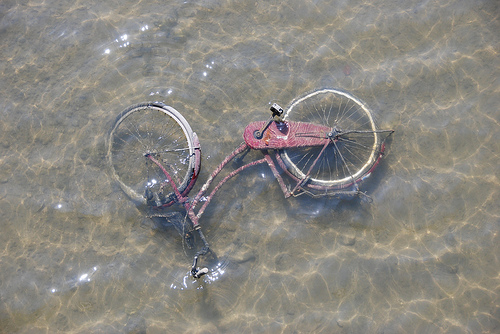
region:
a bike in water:
[101, 87, 392, 274]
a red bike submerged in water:
[103, 88, 389, 278]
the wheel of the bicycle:
[103, 102, 202, 204]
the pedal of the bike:
[253, 100, 283, 138]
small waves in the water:
[261, 226, 488, 313]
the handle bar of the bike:
[183, 244, 210, 279]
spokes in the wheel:
[113, 118, 185, 188]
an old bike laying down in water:
[102, 85, 387, 280]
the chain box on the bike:
[242, 112, 335, 149]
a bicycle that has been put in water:
[103, 86, 383, 277]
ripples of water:
[284, 240, 437, 310]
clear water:
[306, 217, 461, 304]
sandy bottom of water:
[332, 228, 467, 313]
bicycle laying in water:
[109, 88, 375, 278]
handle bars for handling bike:
[177, 253, 224, 285]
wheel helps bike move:
[286, 78, 380, 188]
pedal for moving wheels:
[263, 97, 287, 132]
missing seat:
[278, 187, 316, 225]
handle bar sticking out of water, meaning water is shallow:
[175, 238, 238, 303]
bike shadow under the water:
[185, 284, 230, 331]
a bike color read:
[98, 81, 393, 294]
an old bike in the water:
[93, 80, 399, 286]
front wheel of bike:
[101, 93, 206, 221]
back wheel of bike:
[271, 77, 390, 197]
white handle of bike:
[191, 260, 213, 279]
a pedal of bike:
[259, 89, 289, 142]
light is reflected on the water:
[4, 9, 487, 331]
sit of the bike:
[279, 180, 374, 208]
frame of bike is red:
[145, 137, 295, 206]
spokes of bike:
[119, 118, 185, 188]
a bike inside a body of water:
[96, 76, 401, 282]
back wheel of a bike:
[273, 89, 388, 201]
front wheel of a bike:
[98, 90, 205, 214]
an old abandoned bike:
[89, 69, 415, 284]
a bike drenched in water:
[82, 62, 402, 284]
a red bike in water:
[87, 76, 407, 293]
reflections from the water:
[93, 13, 154, 65]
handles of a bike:
[185, 244, 230, 288]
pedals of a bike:
[252, 96, 300, 138]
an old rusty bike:
[89, 77, 413, 293]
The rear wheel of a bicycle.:
[280, 84, 380, 190]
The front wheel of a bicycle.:
[102, 98, 204, 208]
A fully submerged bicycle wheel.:
[275, 85, 380, 193]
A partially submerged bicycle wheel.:
[100, 83, 205, 211]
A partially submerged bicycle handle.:
[186, 260, 211, 280]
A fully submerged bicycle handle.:
[232, 253, 257, 268]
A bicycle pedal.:
[270, 98, 287, 116]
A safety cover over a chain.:
[247, 115, 335, 149]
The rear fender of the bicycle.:
[272, 139, 389, 192]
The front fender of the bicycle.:
[132, 128, 202, 217]